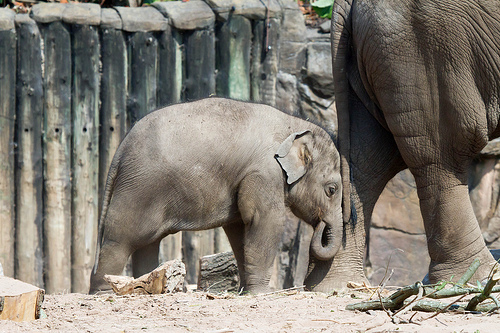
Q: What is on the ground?
A: Tree branches.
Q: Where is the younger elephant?
A: Behind a larger one.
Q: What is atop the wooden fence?
A: Rocks.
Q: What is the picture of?
A: Two elephants beside each other.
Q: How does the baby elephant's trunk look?
A: Curled up.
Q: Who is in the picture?
A: A baby elephant and its mother.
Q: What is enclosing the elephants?
A: A wooden fence.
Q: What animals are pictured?
A: Elephants.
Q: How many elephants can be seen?
A: 2.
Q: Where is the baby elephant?
A: Center of the picture.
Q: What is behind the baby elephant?
A: Fence.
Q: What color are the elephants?
A: Gray.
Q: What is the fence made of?
A: Wood.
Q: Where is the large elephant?
A: Right side of picture.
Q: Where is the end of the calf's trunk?
A: In the calf's mouth.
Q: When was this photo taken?
A: Daytime.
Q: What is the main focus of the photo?
A: Baby elephant.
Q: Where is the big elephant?
A: To the right.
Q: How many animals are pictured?
A: 2.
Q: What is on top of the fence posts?
A: Stones.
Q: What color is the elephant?
A: Brownish gray.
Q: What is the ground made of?
A: Dirt.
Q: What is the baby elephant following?
A: A bigger elephant.